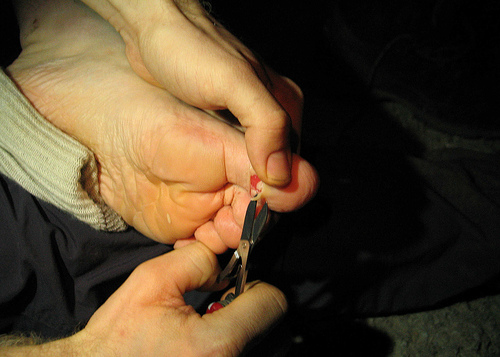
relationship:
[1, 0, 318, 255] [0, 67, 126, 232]
foot on cloth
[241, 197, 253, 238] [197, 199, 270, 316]
blades of metal instrument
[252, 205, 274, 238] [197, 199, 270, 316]
blades of metal instrument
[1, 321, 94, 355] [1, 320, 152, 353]
hairs on arm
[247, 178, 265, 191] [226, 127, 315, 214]
wound on toe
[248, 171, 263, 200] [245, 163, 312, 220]
skin on wound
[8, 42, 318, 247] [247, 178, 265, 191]
foot with wound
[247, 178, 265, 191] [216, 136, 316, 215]
wound on toe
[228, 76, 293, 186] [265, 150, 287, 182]
thumb with finger nail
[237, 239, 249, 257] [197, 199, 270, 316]
hinge of metal instrument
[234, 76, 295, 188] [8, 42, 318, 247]
thumb holding foot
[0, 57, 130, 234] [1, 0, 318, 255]
cloth supporting foot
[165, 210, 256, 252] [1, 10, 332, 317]
toes on foot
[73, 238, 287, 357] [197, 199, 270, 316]
hand holding metal instrument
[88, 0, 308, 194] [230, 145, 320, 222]
hand holding toe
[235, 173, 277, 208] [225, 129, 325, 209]
wound in toe